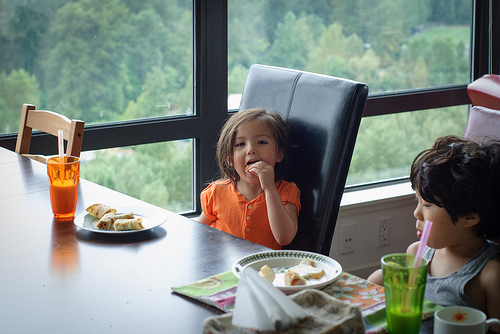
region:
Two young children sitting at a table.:
[197, 93, 499, 318]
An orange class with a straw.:
[39, 127, 80, 224]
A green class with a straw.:
[370, 210, 435, 332]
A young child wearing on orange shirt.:
[185, 100, 305, 260]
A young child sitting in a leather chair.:
[197, 53, 374, 267]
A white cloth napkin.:
[220, 263, 319, 333]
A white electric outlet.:
[374, 216, 397, 248]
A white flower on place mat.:
[353, 280, 389, 311]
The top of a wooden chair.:
[12, 96, 92, 182]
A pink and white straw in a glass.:
[401, 215, 434, 318]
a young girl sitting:
[200, 105, 303, 250]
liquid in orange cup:
[45, 128, 79, 218]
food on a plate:
[75, 203, 167, 234]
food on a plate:
[235, 250, 342, 289]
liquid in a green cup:
[381, 254, 423, 332]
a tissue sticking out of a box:
[231, 266, 306, 328]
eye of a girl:
[257, 135, 268, 145]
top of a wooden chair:
[12, 102, 83, 169]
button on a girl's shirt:
[246, 203, 252, 210]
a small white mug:
[434, 305, 499, 332]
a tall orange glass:
[44, 155, 84, 222]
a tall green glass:
[376, 248, 432, 330]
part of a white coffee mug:
[426, 300, 498, 332]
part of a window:
[227, 0, 473, 105]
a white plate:
[237, 248, 341, 290]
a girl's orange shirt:
[196, 178, 301, 244]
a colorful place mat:
[173, 259, 440, 332]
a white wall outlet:
[375, 214, 396, 247]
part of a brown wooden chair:
[14, 99, 85, 164]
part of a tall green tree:
[420, 33, 470, 82]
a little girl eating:
[195, 109, 316, 246]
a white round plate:
[74, 197, 174, 248]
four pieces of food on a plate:
[85, 196, 152, 234]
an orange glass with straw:
[39, 128, 90, 233]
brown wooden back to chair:
[14, 100, 88, 174]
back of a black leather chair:
[237, 60, 366, 250]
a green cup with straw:
[371, 251, 450, 330]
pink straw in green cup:
[403, 223, 431, 299]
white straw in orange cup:
[56, 126, 74, 168]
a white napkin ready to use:
[221, 263, 334, 332]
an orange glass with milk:
[41, 125, 86, 237]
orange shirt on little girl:
[189, 170, 337, 250]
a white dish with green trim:
[226, 246, 343, 298]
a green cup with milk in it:
[376, 250, 449, 332]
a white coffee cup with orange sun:
[428, 300, 499, 332]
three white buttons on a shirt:
[243, 198, 258, 233]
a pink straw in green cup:
[408, 213, 441, 266]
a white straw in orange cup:
[49, 123, 71, 173]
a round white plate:
[71, 194, 172, 253]